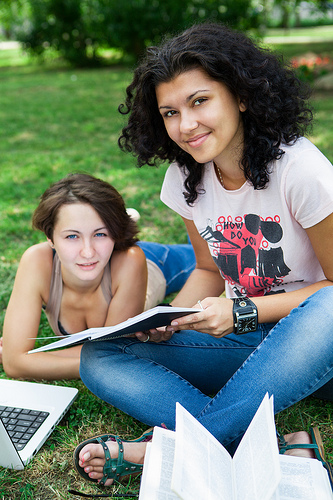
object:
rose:
[289, 50, 330, 79]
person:
[2, 171, 196, 379]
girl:
[74, 21, 333, 486]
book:
[27, 305, 199, 354]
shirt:
[159, 132, 333, 299]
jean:
[71, 338, 206, 459]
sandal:
[73, 425, 155, 489]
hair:
[118, 22, 315, 208]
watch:
[230, 296, 258, 334]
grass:
[0, 63, 92, 152]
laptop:
[0, 376, 80, 472]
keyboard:
[0, 406, 49, 450]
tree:
[0, 0, 268, 65]